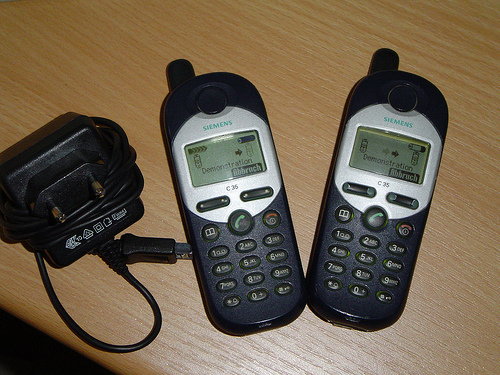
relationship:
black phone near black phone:
[156, 58, 306, 339] [303, 47, 450, 335]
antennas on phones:
[163, 46, 398, 93] [147, 37, 453, 334]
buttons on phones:
[320, 179, 422, 307] [147, 37, 453, 334]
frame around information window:
[173, 105, 281, 222] [183, 127, 268, 188]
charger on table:
[2, 109, 193, 357] [1, 1, 498, 373]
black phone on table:
[156, 58, 306, 339] [1, 1, 498, 373]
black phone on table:
[303, 47, 450, 335] [1, 1, 498, 373]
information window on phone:
[183, 127, 268, 188] [313, 53, 450, 329]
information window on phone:
[183, 127, 268, 188] [167, 57, 304, 334]